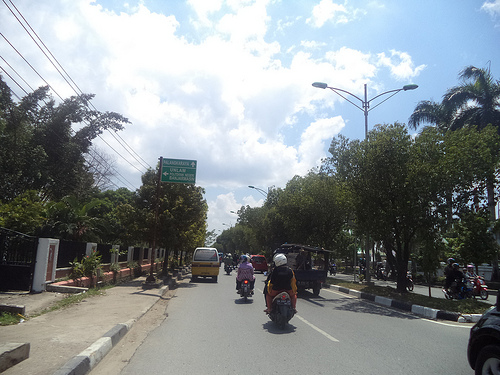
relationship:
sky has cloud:
[3, 1, 500, 247] [382, 50, 424, 82]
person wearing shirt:
[444, 262, 463, 288] [446, 268, 463, 284]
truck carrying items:
[275, 244, 332, 299] [288, 250, 321, 272]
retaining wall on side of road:
[34, 239, 185, 296] [88, 260, 475, 374]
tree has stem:
[328, 123, 442, 293] [395, 233, 404, 261]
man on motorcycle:
[265, 253, 298, 310] [263, 276, 295, 330]